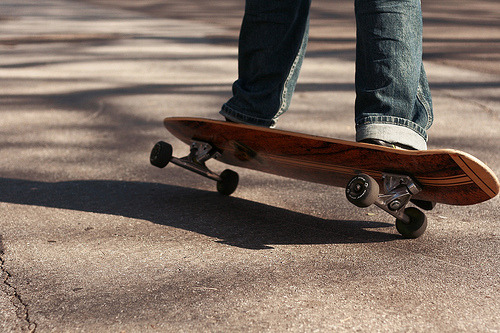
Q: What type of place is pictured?
A: It is a street.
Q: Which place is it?
A: It is a street.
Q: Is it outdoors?
A: Yes, it is outdoors.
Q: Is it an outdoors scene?
A: Yes, it is outdoors.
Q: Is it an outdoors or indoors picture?
A: It is outdoors.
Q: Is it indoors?
A: No, it is outdoors.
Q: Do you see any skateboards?
A: Yes, there is a skateboard.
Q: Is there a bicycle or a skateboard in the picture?
A: Yes, there is a skateboard.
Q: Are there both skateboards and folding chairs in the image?
A: No, there is a skateboard but no folding chairs.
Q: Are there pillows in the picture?
A: No, there are no pillows.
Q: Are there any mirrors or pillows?
A: No, there are no pillows or mirrors.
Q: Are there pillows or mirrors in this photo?
A: No, there are no pillows or mirrors.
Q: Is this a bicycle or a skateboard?
A: This is a skateboard.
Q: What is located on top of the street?
A: The skateboard is on top of the street.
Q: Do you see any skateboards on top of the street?
A: Yes, there is a skateboard on top of the street.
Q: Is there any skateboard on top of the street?
A: Yes, there is a skateboard on top of the street.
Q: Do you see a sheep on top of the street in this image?
A: No, there is a skateboard on top of the street.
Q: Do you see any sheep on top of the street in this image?
A: No, there is a skateboard on top of the street.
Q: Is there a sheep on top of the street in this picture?
A: No, there is a skateboard on top of the street.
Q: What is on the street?
A: The skateboard is on the street.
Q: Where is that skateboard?
A: The skateboard is on the street.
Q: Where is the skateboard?
A: The skateboard is on the street.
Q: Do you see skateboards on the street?
A: Yes, there is a skateboard on the street.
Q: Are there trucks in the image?
A: No, there are no trucks.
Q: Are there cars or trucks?
A: No, there are no trucks or cars.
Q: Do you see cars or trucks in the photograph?
A: No, there are no trucks or cars.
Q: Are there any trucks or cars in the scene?
A: No, there are no trucks or cars.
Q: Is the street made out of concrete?
A: Yes, the street is made of concrete.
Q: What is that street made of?
A: The street is made of concrete.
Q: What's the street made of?
A: The street is made of concrete.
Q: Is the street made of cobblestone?
A: No, the street is made of concrete.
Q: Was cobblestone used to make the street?
A: No, the street is made of concrete.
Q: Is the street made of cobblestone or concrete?
A: The street is made of concrete.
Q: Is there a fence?
A: No, there are no fences.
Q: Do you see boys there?
A: No, there are no boys.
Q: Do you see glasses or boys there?
A: No, there are no boys or glasses.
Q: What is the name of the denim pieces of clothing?
A: The clothing items are jeans.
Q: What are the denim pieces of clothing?
A: The clothing items are jeans.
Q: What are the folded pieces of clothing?
A: The clothing items are jeans.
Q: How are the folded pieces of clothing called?
A: The clothing items are jeans.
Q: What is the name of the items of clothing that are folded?
A: The clothing items are jeans.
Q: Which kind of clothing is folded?
A: The clothing is jeans.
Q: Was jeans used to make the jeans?
A: Yes, the jeans are made of jeans.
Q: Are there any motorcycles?
A: No, there are no motorcycles.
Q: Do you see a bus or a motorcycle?
A: No, there are no motorcycles or buses.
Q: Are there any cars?
A: No, there are no cars.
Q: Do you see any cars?
A: No, there are no cars.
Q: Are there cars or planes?
A: No, there are no cars or planes.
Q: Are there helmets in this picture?
A: No, there are no helmets.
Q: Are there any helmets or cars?
A: No, there are no helmets or cars.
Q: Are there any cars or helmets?
A: No, there are no helmets or cars.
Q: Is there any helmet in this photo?
A: No, there are no helmets.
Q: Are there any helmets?
A: No, there are no helmets.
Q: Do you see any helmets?
A: No, there are no helmets.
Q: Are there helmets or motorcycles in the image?
A: No, there are no helmets or motorcycles.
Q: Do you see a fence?
A: No, there are no fences.